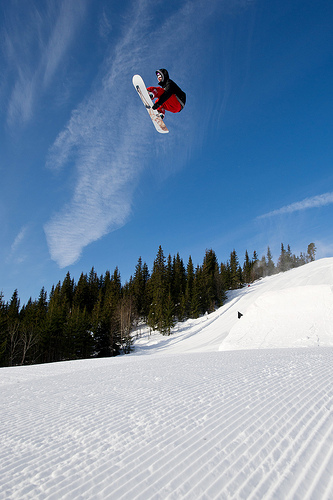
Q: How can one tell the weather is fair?
A: The sky is clear blue.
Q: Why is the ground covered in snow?
A: The season is winter.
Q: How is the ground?
A: Grooved.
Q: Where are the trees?
A: In the back.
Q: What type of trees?
A: Evergreen.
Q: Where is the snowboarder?
A: In the air.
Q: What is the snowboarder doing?
A: Jumping.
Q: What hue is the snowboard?
A: Orange and white.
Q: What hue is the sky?
A: Blue.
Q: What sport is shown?
A: Snowboarding.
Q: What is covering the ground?
A: Snow.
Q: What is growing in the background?
A: Trees.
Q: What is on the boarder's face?
A: Sunglasses.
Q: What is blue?
A: Sky.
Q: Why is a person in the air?
A: Person is snowboarding.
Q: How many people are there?
A: One.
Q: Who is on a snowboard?
A: A person.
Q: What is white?
A: Snowboard.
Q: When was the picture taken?
A: Daytime.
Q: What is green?
A: Trees.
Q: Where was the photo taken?
A: On the ski slope.